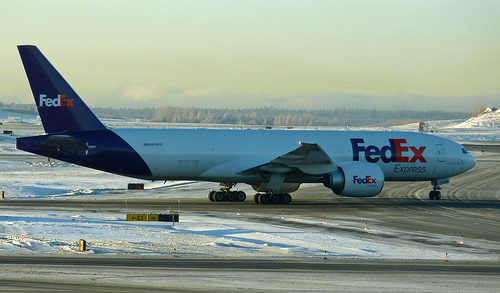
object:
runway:
[0, 146, 499, 292]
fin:
[15, 44, 106, 132]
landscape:
[1, 100, 496, 291]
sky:
[0, 1, 498, 111]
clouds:
[109, 70, 475, 104]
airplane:
[13, 44, 476, 206]